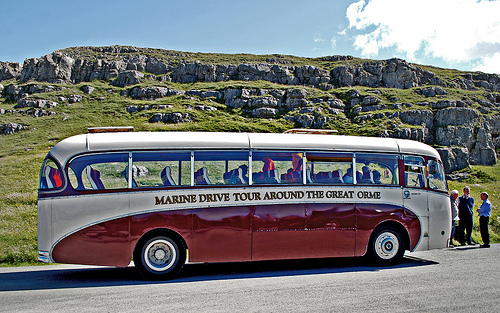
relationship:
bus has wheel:
[33, 131, 456, 285] [134, 230, 184, 280]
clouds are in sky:
[347, 2, 498, 77] [1, 3, 497, 66]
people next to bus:
[445, 181, 497, 246] [33, 131, 456, 285]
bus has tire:
[33, 131, 456, 285] [368, 220, 407, 266]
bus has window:
[35, 125, 453, 280] [128, 147, 194, 189]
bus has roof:
[35, 125, 453, 280] [47, 123, 441, 154]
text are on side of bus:
[154, 190, 382, 206] [35, 125, 453, 280]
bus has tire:
[33, 131, 456, 285] [134, 225, 190, 282]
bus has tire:
[33, 131, 456, 285] [366, 212, 404, 265]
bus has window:
[33, 131, 456, 285] [37, 149, 62, 193]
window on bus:
[125, 158, 188, 194] [35, 125, 453, 280]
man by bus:
[443, 186, 488, 242] [35, 125, 453, 280]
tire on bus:
[132, 227, 186, 279] [35, 125, 453, 280]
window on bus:
[128, 147, 194, 189] [56, 123, 487, 283]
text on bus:
[154, 190, 382, 206] [35, 125, 453, 280]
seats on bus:
[81, 156, 129, 202] [39, 140, 474, 267]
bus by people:
[35, 125, 453, 280] [435, 183, 499, 245]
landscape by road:
[96, 55, 379, 122] [48, 257, 486, 311]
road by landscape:
[58, 268, 419, 311] [54, 46, 456, 125]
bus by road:
[35, 125, 453, 280] [133, 270, 372, 310]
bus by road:
[35, 125, 453, 280] [58, 276, 419, 313]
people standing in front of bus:
[449, 189, 460, 248] [33, 131, 456, 285]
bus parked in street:
[33, 131, 456, 285] [0, 257, 498, 311]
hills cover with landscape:
[0, 44, 217, 125] [96, 55, 379, 122]